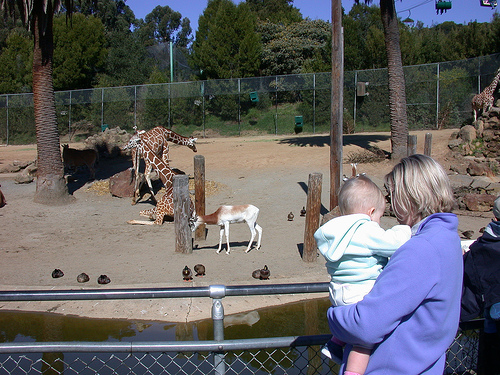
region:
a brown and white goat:
[181, 201, 266, 254]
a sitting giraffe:
[120, 124, 202, 224]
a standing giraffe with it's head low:
[125, 124, 200, 207]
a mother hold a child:
[309, 156, 464, 373]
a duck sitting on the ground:
[47, 264, 64, 281]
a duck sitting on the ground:
[71, 268, 89, 285]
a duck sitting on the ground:
[94, 271, 111, 287]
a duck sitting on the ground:
[249, 267, 269, 281]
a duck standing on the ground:
[177, 262, 192, 282]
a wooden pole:
[167, 167, 192, 257]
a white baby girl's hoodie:
[312, 213, 412, 278]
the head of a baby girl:
[333, 176, 386, 221]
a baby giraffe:
[192, 202, 268, 252]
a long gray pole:
[0, 278, 333, 303]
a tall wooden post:
[191, 152, 208, 239]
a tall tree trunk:
[28, 0, 72, 206]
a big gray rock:
[457, 122, 474, 142]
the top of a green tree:
[142, 5, 179, 43]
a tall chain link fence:
[1, 50, 497, 145]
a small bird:
[284, 210, 297, 222]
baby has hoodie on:
[280, 161, 394, 302]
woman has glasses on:
[373, 160, 446, 235]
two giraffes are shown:
[122, 124, 179, 229]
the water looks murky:
[16, 297, 66, 335]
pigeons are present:
[180, 223, 297, 335]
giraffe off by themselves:
[435, 58, 495, 111]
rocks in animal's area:
[438, 136, 498, 193]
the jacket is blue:
[469, 232, 498, 289]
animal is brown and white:
[194, 203, 284, 285]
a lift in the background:
[436, 0, 462, 23]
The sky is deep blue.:
[301, 0, 326, 10]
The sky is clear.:
[302, 0, 327, 15]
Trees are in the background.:
[203, 5, 315, 73]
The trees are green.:
[206, 14, 306, 74]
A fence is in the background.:
[121, 77, 308, 122]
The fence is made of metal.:
[138, 77, 240, 124]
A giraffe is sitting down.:
[113, 129, 201, 224]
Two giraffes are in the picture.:
[107, 120, 214, 229]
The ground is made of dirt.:
[234, 152, 294, 191]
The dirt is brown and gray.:
[233, 157, 295, 193]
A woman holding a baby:
[316, 151, 474, 371]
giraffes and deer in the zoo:
[117, 116, 267, 252]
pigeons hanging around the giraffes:
[172, 262, 284, 282]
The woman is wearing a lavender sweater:
[390, 212, 466, 370]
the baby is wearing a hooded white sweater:
[312, 214, 417, 292]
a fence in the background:
[197, 70, 337, 129]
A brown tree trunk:
[24, 27, 76, 216]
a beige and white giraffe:
[466, 52, 497, 127]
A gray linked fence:
[85, 330, 305, 372]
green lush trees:
[200, 13, 342, 69]